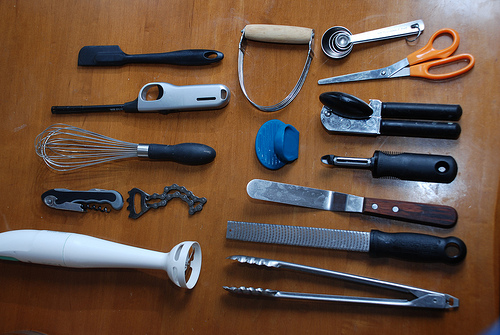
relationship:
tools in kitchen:
[8, 14, 445, 331] [20, 19, 440, 318]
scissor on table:
[297, 32, 482, 95] [34, 9, 478, 332]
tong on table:
[218, 260, 469, 302] [34, 9, 478, 332]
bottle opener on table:
[132, 180, 227, 221] [34, 9, 478, 332]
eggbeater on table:
[24, 108, 220, 180] [34, 9, 478, 332]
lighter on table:
[33, 61, 232, 127] [34, 9, 478, 332]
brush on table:
[41, 204, 209, 314] [34, 9, 478, 332]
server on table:
[206, 2, 336, 131] [34, 9, 478, 332]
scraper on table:
[219, 205, 476, 247] [34, 9, 478, 332]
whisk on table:
[47, 182, 134, 233] [34, 9, 478, 332]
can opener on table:
[302, 80, 488, 159] [34, 9, 478, 332]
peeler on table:
[302, 141, 475, 179] [34, 9, 478, 332]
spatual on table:
[240, 114, 307, 172] [34, 9, 478, 332]